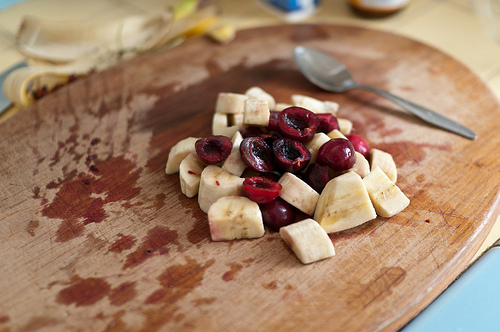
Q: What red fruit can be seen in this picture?
A: Cherries.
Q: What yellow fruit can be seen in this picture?
A: Bananas.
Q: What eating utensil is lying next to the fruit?
A: Spoon.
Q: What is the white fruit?
A: Banana.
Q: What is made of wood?
A: Cutting board.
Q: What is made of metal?
A: Spoon.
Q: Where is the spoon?
A: On the cutting board.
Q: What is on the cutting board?
A: Fruit.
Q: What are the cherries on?
A: Cutting board.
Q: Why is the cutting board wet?
A: Juice from fruit.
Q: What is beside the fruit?
A: A spoon.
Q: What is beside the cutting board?
A: Banana peel.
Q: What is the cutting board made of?
A: Wood.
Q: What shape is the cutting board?
A: Oval.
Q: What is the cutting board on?
A: A table.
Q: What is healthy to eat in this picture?
A: Fruit.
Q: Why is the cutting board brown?
A: It's made of wood.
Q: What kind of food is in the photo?
A: Fruit.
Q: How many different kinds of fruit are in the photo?
A: Two.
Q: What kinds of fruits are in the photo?
A: Cherries and bananas.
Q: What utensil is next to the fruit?
A: Spoon.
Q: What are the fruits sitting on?
A: Cutting board.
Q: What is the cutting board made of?
A: Wood.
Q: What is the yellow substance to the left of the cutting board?
A: Banana peel.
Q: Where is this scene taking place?
A: In a kitchen.